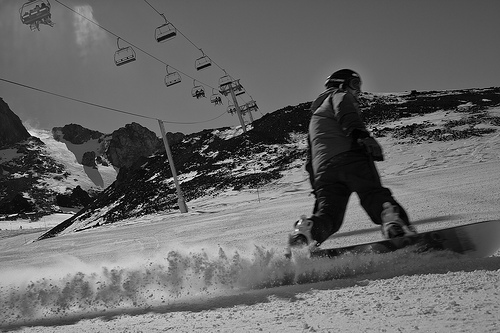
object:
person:
[283, 68, 412, 258]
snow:
[2, 86, 499, 295]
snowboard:
[251, 216, 499, 285]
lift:
[16, 1, 51, 33]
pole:
[153, 119, 191, 213]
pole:
[226, 80, 249, 135]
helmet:
[323, 68, 361, 90]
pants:
[302, 155, 404, 240]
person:
[36, 2, 48, 18]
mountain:
[1, 85, 495, 241]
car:
[154, 16, 178, 43]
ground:
[3, 167, 496, 332]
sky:
[2, 1, 499, 129]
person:
[198, 89, 205, 99]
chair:
[190, 82, 206, 100]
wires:
[1, 79, 230, 127]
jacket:
[303, 89, 373, 176]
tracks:
[390, 139, 493, 175]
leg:
[297, 160, 348, 245]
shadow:
[315, 213, 456, 239]